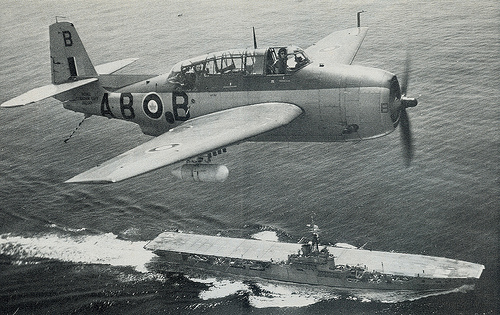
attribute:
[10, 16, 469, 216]
airplane — small, airborne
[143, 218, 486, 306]
boat — large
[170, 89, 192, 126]
letter — black 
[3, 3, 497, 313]
water — dark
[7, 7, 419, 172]
plane — old fashioned, flying, small, airborne